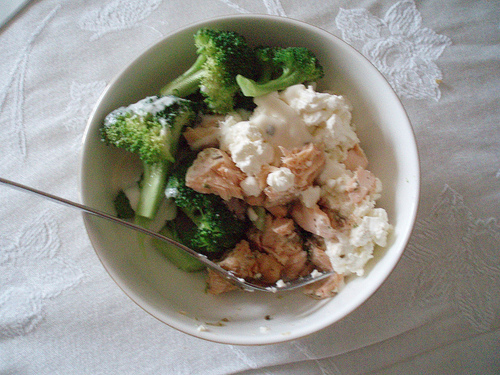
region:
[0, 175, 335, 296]
a metal fork in the bowl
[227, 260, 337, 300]
the tines of a fork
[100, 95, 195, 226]
a piece of broccoli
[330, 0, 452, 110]
a white floral pattern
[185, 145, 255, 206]
a piece of chicken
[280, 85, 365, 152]
a piece of cauliflower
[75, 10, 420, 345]
a white bowl on the table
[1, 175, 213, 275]
the handle of a fork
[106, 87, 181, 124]
frost on the broccoli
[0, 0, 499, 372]
a white tablecloth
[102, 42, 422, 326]
A bowl full of food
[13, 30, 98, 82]
A thin white table cloth.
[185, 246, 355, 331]
a silver fork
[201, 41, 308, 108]
Cooked broccoli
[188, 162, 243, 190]
A chuck of tune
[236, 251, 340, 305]
The fork is wedge into the food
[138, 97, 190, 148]
A broccoli covered in sauce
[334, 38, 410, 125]
A smooth porcelain bowl.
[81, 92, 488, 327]
This bowl is lying on top a table cloth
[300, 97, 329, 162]
Some white creamy food.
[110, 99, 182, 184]
a piece of broccoli with ranch dressing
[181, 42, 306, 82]
two pieces of raw broccoli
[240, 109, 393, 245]
white cheese with dressing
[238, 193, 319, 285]
chunks of chicken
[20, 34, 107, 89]
a white patterned table cloth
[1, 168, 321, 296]
a silver fork in a bowl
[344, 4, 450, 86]
a white flower on a tablecloth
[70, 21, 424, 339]
a white bowl filled with food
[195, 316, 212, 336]
a spot of white cheese on the interior of a bowl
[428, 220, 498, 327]
a stitched flower to the right of a bowl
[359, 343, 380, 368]
the linen is white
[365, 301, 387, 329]
the linen is white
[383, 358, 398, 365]
the linen is white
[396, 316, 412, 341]
the linen is white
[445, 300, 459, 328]
the linen is white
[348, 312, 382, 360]
the linen is white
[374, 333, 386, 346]
the linen is white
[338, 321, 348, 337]
the linen is white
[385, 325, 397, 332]
the linen is white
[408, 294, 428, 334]
the linen is white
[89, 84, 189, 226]
broccoli in a bowl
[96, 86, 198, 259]
broccoli covered with ranch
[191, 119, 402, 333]
tuna fish in a bowl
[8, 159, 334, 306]
fork in a bowl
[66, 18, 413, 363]
bowl of food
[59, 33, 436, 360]
white bowl with food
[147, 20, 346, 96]
broccoli in a white bowl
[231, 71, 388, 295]
tuna fish in a white bowl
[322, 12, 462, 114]
flowers on a white cover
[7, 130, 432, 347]
fork in a bowl with food in it